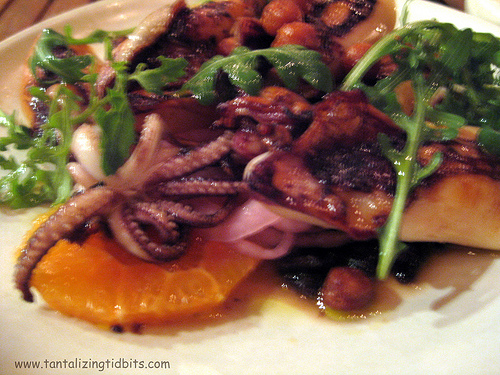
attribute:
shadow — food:
[430, 262, 482, 309]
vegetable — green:
[19, 74, 126, 189]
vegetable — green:
[379, 19, 476, 260]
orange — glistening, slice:
[54, 237, 218, 337]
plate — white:
[1, 1, 499, 373]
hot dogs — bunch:
[45, 260, 201, 288]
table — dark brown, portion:
[3, 9, 38, 42]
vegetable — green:
[328, 18, 482, 296]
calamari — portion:
[1, 108, 261, 308]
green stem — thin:
[366, 17, 492, 285]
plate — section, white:
[14, 306, 497, 374]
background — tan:
[2, 341, 495, 375]